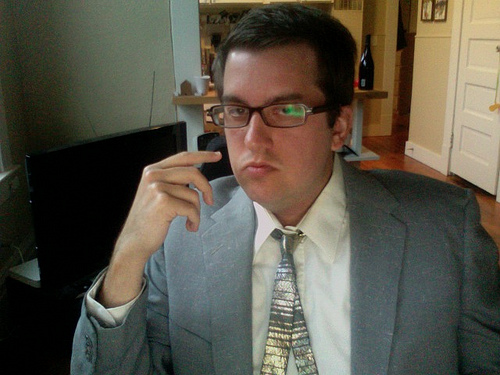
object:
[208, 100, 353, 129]
glasses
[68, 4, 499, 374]
man.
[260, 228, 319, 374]
tie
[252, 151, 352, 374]
shirt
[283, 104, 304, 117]
reflection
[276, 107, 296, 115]
eyes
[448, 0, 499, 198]
door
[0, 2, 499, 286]
room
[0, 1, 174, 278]
wall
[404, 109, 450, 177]
base board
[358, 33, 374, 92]
bottle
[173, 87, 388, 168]
table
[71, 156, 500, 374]
suit coat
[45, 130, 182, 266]
screen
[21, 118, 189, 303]
tv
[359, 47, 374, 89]
wine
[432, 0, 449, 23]
picture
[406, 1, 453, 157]
wall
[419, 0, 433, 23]
picture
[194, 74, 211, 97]
cup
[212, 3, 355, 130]
hair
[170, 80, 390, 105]
counter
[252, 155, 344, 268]
collar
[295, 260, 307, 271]
buttons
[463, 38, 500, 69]
panels.